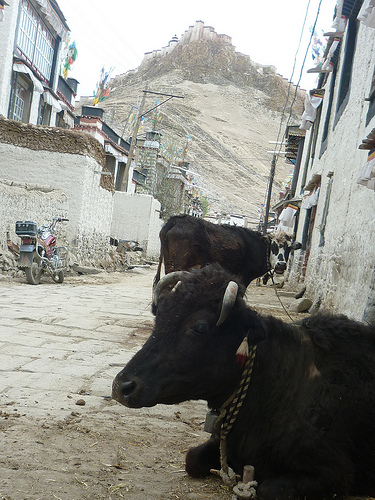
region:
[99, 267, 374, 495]
cow is sitting down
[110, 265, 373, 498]
cattle is sitting down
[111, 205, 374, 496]
cattle on the street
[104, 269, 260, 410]
head of a cow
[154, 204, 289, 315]
cow on the street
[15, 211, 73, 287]
dirty old motorcycle parked on street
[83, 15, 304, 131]
building on a top cliff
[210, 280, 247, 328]
horns of a cattle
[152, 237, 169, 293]
tail of a cow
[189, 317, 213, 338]
eye of a cattle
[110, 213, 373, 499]
the two dark colored bulls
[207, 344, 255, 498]
the rope attached to the bull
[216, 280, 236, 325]
the horn on the bull's head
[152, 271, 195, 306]
the horn on the bull's head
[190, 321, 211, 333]
the eye on the bull's face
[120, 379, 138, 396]
the nostril on the bull's face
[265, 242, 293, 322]
the rope attached to the bull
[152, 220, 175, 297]
the tail on the bull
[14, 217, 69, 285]
the motorcycle parked on the side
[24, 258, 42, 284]
the tire on the motorcycle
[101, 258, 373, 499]
cow laying on the ground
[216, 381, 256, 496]
rope connected to the cow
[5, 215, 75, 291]
motorcycle near the building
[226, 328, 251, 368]
tag on the collar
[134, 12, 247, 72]
building on the hill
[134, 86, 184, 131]
wooden pole on the street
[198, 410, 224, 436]
bell on the cow's neck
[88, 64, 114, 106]
colorful decoration on the building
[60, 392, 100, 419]
rocks on the road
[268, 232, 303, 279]
black and white face of the cow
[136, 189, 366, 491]
cows on the ground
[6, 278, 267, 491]
road for pedestrians and vehicles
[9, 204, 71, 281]
motorized bike on road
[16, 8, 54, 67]
windows on a building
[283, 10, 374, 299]
building next to cows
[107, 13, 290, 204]
mountain with buildings on top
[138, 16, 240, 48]
buildings on top of mountain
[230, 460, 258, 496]
post where cow is tied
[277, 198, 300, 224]
banners hanging off building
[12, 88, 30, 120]
window on the building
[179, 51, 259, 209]
very steep and rocky hillside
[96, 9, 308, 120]
historic city on top of a hillside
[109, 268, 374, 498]
cattle laying down and tied to a small post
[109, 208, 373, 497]
two cattle tied in place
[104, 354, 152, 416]
nose of a black cow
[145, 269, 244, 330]
two cattle horns that turn downwards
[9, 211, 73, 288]
dilapidated and small motorcycle with storage on the back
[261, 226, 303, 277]
cow with a white and black face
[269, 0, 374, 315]
side of a two story building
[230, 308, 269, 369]
identifying tag on a cow's ear